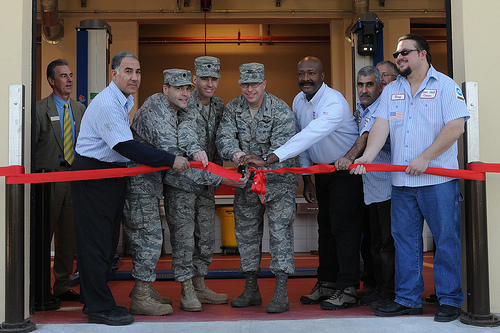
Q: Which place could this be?
A: It is a store.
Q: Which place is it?
A: It is a store.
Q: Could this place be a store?
A: Yes, it is a store.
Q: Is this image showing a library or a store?
A: It is showing a store.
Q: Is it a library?
A: No, it is a store.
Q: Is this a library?
A: No, it is a store.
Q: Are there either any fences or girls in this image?
A: No, there are no girls or fences.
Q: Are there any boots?
A: Yes, there are boots.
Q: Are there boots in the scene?
A: Yes, there are boots.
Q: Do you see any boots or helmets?
A: Yes, there are boots.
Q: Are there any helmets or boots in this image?
A: Yes, there are boots.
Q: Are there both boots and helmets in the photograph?
A: No, there are boots but no helmets.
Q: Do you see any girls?
A: No, there are no girls.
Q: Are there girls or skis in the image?
A: No, there are no girls or skis.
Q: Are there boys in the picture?
A: No, there are no boys.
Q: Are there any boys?
A: No, there are no boys.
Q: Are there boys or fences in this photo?
A: No, there are no boys or fences.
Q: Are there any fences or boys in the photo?
A: No, there are no boys or fences.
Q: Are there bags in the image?
A: No, there are no bags.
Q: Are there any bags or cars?
A: No, there are no bags or cars.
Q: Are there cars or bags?
A: No, there are no bags or cars.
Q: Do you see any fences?
A: No, there are no fences.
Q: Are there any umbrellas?
A: No, there are no umbrellas.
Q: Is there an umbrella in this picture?
A: No, there are no umbrellas.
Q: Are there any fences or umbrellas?
A: No, there are no umbrellas or fences.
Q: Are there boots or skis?
A: Yes, there are boots.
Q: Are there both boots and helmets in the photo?
A: No, there are boots but no helmets.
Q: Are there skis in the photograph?
A: No, there are no skis.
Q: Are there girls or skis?
A: No, there are no skis or girls.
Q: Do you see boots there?
A: Yes, there are boots.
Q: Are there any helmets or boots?
A: Yes, there are boots.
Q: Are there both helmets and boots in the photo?
A: No, there are boots but no helmets.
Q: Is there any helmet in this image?
A: No, there are no helmets.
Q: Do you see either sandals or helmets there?
A: No, there are no helmets or sandals.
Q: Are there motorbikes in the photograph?
A: No, there are no motorbikes.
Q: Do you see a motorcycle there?
A: No, there are no motorcycles.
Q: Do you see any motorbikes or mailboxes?
A: No, there are no motorbikes or mailboxes.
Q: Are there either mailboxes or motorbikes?
A: No, there are no motorbikes or mailboxes.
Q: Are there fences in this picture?
A: No, there are no fences.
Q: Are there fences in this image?
A: No, there are no fences.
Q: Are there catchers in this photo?
A: No, there are no catchers.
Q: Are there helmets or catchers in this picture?
A: No, there are no catchers or helmets.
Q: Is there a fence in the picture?
A: No, there are no fences.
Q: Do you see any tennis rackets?
A: No, there are no tennis rackets.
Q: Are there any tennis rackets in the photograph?
A: No, there are no tennis rackets.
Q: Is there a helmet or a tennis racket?
A: No, there are no rackets or helmets.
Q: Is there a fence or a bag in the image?
A: No, there are no fences or bags.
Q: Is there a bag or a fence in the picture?
A: No, there are no fences or bags.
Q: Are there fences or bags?
A: No, there are no fences or bags.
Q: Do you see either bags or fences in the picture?
A: No, there are no fences or bags.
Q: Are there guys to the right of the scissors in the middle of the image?
A: Yes, there are guys to the right of the scissors.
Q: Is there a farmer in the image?
A: No, there are no farmers.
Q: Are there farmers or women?
A: No, there are no farmers or women.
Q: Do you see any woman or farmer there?
A: No, there are no farmers or women.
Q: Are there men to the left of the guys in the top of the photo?
A: Yes, there is a man to the left of the guys.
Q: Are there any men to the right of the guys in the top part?
A: No, the man is to the left of the guys.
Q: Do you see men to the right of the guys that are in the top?
A: No, the man is to the left of the guys.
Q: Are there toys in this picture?
A: No, there are no toys.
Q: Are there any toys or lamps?
A: No, there are no toys or lamps.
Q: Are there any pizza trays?
A: No, there are no pizza trays.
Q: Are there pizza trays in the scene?
A: No, there are no pizza trays.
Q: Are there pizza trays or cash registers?
A: No, there are no pizza trays or cash registers.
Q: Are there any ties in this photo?
A: Yes, there is a tie.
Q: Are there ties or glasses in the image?
A: Yes, there is a tie.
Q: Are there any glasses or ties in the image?
A: Yes, there is a tie.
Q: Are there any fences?
A: No, there are no fences.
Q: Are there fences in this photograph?
A: No, there are no fences.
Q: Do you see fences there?
A: No, there are no fences.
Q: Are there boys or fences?
A: No, there are no fences or boys.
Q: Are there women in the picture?
A: No, there are no women.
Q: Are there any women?
A: No, there are no women.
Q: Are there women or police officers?
A: No, there are no women or police officers.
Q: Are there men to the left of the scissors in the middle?
A: Yes, there are men to the left of the scissors.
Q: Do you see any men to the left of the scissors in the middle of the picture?
A: Yes, there are men to the left of the scissors.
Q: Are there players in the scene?
A: No, there are no players.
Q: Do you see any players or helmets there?
A: No, there are no players or helmets.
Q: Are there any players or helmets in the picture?
A: No, there are no players or helmets.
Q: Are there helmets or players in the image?
A: No, there are no players or helmets.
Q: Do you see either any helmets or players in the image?
A: No, there are no players or helmets.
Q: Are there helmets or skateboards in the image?
A: No, there are no helmets or skateboards.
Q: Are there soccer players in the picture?
A: No, there are no soccer players.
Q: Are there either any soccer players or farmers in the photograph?
A: No, there are no soccer players or farmers.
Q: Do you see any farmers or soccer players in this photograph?
A: No, there are no soccer players or farmers.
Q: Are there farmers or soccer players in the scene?
A: No, there are no soccer players or farmers.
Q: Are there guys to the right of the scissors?
A: Yes, there are guys to the right of the scissors.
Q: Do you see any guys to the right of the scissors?
A: Yes, there are guys to the right of the scissors.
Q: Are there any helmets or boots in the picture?
A: Yes, there are boots.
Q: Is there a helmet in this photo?
A: No, there are no helmets.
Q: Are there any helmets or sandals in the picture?
A: No, there are no helmets or sandals.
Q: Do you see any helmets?
A: No, there are no helmets.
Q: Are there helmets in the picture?
A: No, there are no helmets.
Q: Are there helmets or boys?
A: No, there are no helmets or boys.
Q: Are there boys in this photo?
A: No, there are no boys.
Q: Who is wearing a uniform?
A: The man is wearing a uniform.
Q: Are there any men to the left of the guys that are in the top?
A: Yes, there is a man to the left of the guys.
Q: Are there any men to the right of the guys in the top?
A: No, the man is to the left of the guys.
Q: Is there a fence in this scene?
A: No, there are no fences.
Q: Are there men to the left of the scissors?
A: Yes, there is a man to the left of the scissors.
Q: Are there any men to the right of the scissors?
A: No, the man is to the left of the scissors.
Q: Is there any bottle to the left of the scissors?
A: No, there is a man to the left of the scissors.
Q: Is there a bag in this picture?
A: No, there are no bags.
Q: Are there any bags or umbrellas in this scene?
A: No, there are no bags or umbrellas.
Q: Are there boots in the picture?
A: Yes, there are boots.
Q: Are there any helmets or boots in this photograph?
A: Yes, there are boots.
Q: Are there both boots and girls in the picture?
A: No, there are boots but no girls.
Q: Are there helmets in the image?
A: No, there are no helmets.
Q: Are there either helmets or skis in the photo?
A: No, there are no helmets or skis.